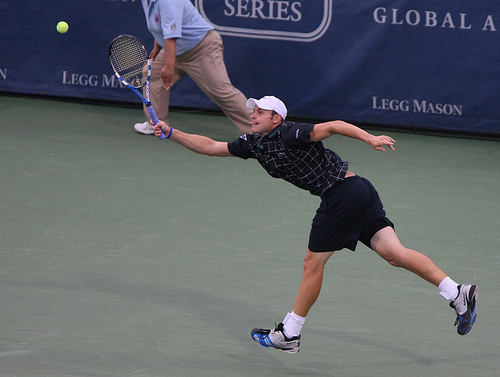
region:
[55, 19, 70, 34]
this is a tennis ball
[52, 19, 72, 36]
the ball is small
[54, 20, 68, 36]
the ball is green in color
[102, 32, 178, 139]
this is a racket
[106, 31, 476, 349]
this is a man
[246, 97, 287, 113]
this is a cap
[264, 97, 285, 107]
the cap is white in color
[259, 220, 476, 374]
the feet are apart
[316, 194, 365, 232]
the short is black in color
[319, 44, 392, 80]
the wall is blue in color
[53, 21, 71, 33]
A green tennis ball.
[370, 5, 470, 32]
The word GLOBAL on the wall.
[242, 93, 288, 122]
The white cap on a man's head.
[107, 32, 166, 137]
A blue and white tennis racket.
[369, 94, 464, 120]
LEGG MASON written on the wall behind the man.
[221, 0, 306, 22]
The word SERIES.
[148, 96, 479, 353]
A man in a white cap playing tennis.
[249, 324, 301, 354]
The left shoe of a man playing tennis.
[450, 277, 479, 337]
The right shoe on a man playing tennis.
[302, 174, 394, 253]
A pair of black shorts on a man playing tennis.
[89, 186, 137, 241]
part of a court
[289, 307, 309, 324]
edge of a sock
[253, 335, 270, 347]
edge of a shoe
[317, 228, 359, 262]
edge of a short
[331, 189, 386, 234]
part of a short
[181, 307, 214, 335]
part of a floor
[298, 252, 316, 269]
part of a knee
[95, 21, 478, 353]
tennis player moving towards the ball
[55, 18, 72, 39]
yellow tennis ball about to be hot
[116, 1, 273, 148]
person wearing long pants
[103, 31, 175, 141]
tennis racquet in persons hand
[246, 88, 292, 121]
white cap on players head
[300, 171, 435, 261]
player wearing short pants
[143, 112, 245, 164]
right arm holding tennis racquet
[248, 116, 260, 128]
player's tongue sticking out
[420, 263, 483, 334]
right foot in the air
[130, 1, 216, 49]
person wearing a light blue shirt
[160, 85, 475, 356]
this is a tennis player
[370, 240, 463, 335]
the leg is behind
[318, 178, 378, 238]
he is wearing shorts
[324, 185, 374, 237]
the shorts are black in color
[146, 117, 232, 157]
the hand is in front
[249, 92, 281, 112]
he is wearing a cap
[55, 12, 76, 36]
this is a ball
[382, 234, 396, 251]
the player is light skinned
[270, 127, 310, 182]
the t shirt is black in color